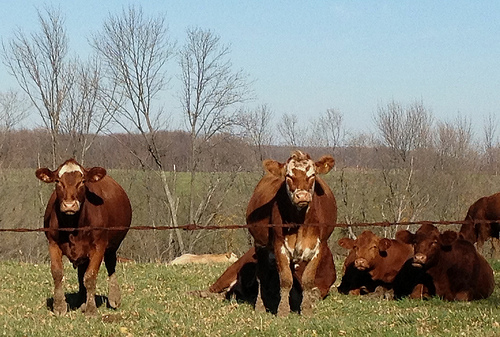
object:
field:
[138, 271, 187, 331]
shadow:
[223, 261, 279, 315]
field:
[1, 266, 91, 330]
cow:
[33, 157, 133, 318]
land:
[0, 118, 499, 188]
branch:
[159, 163, 246, 255]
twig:
[186, 188, 215, 253]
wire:
[0, 219, 500, 233]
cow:
[243, 149, 339, 318]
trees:
[0, 4, 112, 191]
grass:
[279, 295, 499, 330]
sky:
[2, 5, 498, 147]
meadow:
[1, 154, 31, 216]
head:
[34, 158, 108, 216]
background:
[0, 0, 500, 176]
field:
[0, 165, 498, 337]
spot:
[57, 163, 83, 178]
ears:
[34, 167, 55, 183]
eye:
[54, 179, 60, 183]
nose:
[61, 202, 78, 210]